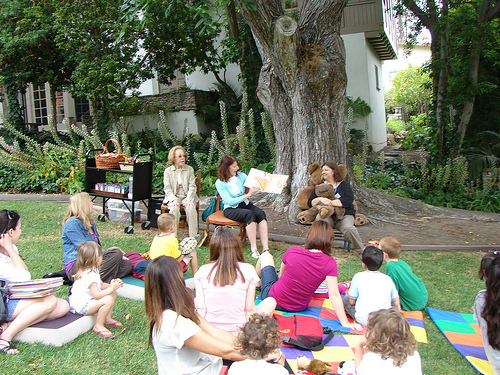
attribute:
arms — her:
[304, 192, 354, 212]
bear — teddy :
[295, 164, 338, 245]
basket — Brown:
[95, 139, 123, 167]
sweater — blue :
[214, 181, 249, 201]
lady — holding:
[313, 165, 366, 245]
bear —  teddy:
[316, 185, 332, 221]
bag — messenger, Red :
[273, 315, 322, 344]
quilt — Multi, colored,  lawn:
[423, 305, 486, 372]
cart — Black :
[74, 150, 163, 228]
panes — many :
[29, 83, 54, 123]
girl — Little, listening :
[66, 241, 116, 334]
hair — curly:
[246, 318, 271, 352]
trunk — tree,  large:
[271, 124, 333, 180]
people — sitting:
[4, 147, 445, 370]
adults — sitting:
[146, 226, 344, 372]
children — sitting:
[134, 285, 424, 373]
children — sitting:
[143, 230, 283, 372]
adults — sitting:
[3, 180, 133, 312]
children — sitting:
[130, 230, 407, 372]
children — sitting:
[130, 247, 415, 372]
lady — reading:
[203, 156, 283, 252]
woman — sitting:
[156, 142, 205, 243]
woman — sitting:
[305, 162, 369, 252]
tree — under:
[240, 3, 354, 169]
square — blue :
[424, 310, 458, 325]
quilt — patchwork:
[427, 298, 484, 371]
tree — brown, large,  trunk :
[244, 14, 346, 173]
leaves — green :
[5, 4, 228, 92]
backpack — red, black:
[268, 302, 326, 360]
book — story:
[244, 163, 287, 205]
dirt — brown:
[374, 196, 498, 236]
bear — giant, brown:
[303, 155, 349, 226]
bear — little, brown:
[318, 181, 347, 224]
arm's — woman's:
[307, 195, 348, 206]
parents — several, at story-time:
[5, 197, 466, 307]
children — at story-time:
[24, 140, 495, 361]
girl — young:
[76, 240, 126, 339]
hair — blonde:
[69, 239, 101, 267]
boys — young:
[357, 223, 417, 307]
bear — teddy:
[308, 179, 343, 216]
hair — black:
[0, 202, 19, 229]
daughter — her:
[69, 240, 127, 339]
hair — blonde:
[154, 209, 176, 230]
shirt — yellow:
[142, 230, 188, 258]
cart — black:
[82, 144, 157, 234]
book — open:
[246, 166, 291, 194]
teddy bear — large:
[307, 177, 339, 248]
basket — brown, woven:
[90, 136, 122, 169]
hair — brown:
[306, 220, 335, 240]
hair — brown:
[144, 254, 201, 334]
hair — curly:
[237, 310, 425, 364]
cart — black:
[87, 159, 156, 235]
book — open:
[248, 164, 291, 201]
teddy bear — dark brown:
[297, 160, 343, 233]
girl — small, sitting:
[70, 240, 124, 338]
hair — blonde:
[74, 243, 97, 277]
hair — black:
[362, 243, 384, 272]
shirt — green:
[387, 253, 427, 307]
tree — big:
[57, 2, 358, 225]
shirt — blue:
[60, 215, 100, 262]